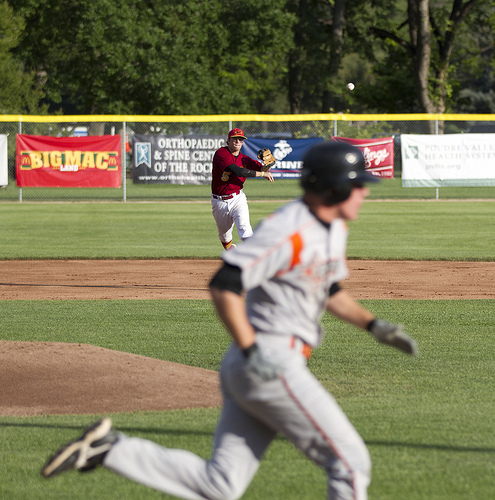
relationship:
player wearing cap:
[210, 127, 280, 250] [228, 127, 248, 141]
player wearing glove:
[210, 127, 280, 250] [255, 143, 276, 166]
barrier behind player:
[3, 112, 495, 192] [210, 127, 280, 250]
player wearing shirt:
[210, 127, 280, 250] [206, 148, 262, 192]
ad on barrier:
[17, 125, 124, 199] [3, 112, 495, 192]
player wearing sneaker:
[47, 138, 422, 499] [40, 419, 120, 475]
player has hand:
[210, 127, 280, 250] [264, 169, 276, 181]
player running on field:
[47, 138, 422, 499] [0, 201, 488, 499]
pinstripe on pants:
[275, 368, 359, 495] [108, 331, 381, 495]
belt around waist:
[215, 188, 240, 202] [208, 187, 246, 206]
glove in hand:
[255, 143, 276, 166] [259, 148, 272, 166]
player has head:
[47, 138, 422, 499] [297, 141, 377, 229]